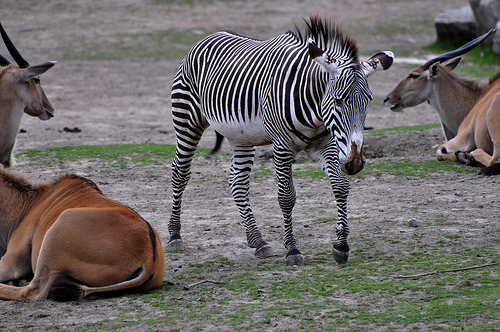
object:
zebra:
[164, 15, 395, 266]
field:
[0, 0, 500, 331]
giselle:
[384, 28, 498, 174]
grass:
[17, 140, 174, 173]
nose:
[349, 141, 360, 173]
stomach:
[204, 111, 270, 147]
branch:
[396, 262, 500, 278]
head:
[383, 64, 438, 116]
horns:
[420, 27, 498, 70]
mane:
[287, 14, 362, 63]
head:
[305, 40, 395, 175]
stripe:
[234, 153, 256, 158]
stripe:
[233, 157, 254, 162]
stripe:
[172, 118, 201, 137]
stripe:
[177, 134, 198, 148]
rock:
[434, 4, 478, 50]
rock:
[467, 0, 500, 52]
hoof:
[331, 246, 350, 265]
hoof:
[284, 254, 306, 268]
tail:
[50, 273, 149, 304]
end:
[47, 279, 85, 302]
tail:
[208, 130, 227, 156]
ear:
[307, 36, 343, 74]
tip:
[307, 38, 316, 44]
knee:
[276, 182, 297, 208]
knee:
[327, 175, 350, 197]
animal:
[0, 167, 166, 301]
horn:
[1, 21, 32, 69]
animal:
[0, 23, 56, 166]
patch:
[55, 61, 169, 143]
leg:
[271, 142, 305, 266]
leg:
[309, 138, 351, 267]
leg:
[167, 74, 212, 247]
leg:
[229, 138, 278, 258]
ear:
[360, 47, 395, 76]